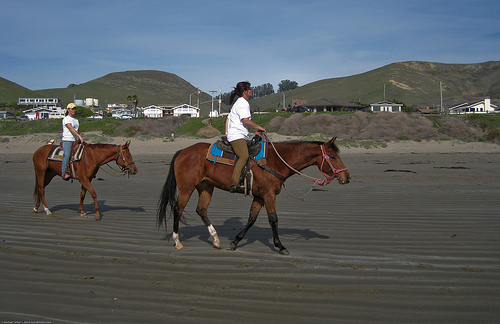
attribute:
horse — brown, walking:
[173, 140, 351, 255]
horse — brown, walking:
[32, 144, 139, 221]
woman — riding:
[224, 81, 268, 195]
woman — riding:
[60, 101, 85, 183]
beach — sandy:
[1, 152, 500, 324]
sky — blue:
[1, 2, 497, 99]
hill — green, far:
[36, 70, 231, 105]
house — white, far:
[449, 97, 496, 115]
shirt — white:
[226, 97, 254, 142]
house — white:
[23, 104, 62, 121]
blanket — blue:
[210, 140, 266, 160]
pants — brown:
[230, 138, 249, 187]